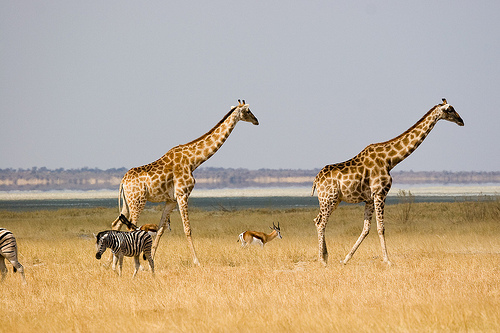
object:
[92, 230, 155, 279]
zebra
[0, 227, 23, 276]
zebra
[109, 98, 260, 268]
brown giraffe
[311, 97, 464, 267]
giraffe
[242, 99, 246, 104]
ear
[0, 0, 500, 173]
sky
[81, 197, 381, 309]
field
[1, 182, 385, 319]
field